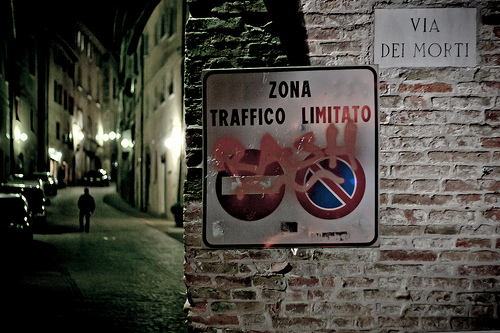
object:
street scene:
[1, 0, 499, 332]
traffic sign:
[202, 64, 381, 247]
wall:
[177, 1, 499, 332]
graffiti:
[213, 118, 360, 200]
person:
[78, 187, 98, 233]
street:
[1, 181, 190, 332]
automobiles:
[0, 168, 111, 249]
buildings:
[1, 1, 185, 220]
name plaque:
[374, 8, 479, 67]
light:
[19, 132, 30, 141]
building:
[1, 1, 44, 177]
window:
[120, 136, 136, 152]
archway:
[119, 160, 135, 206]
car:
[78, 167, 111, 187]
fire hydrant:
[169, 203, 185, 229]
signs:
[201, 8, 477, 248]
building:
[45, 1, 121, 181]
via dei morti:
[381, 16, 471, 58]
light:
[68, 124, 85, 147]